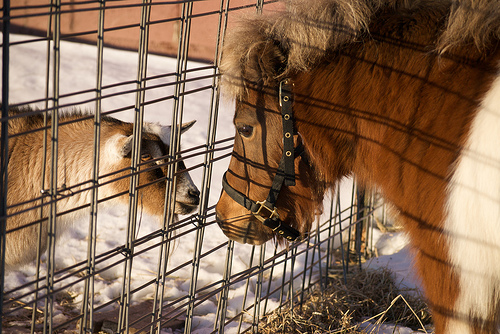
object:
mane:
[225, 0, 500, 50]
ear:
[113, 133, 133, 157]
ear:
[170, 119, 197, 135]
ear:
[246, 40, 292, 80]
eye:
[238, 124, 253, 137]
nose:
[188, 188, 200, 198]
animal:
[4, 102, 199, 269]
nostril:
[217, 221, 226, 229]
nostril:
[188, 190, 200, 198]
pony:
[208, 0, 500, 334]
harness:
[214, 32, 301, 242]